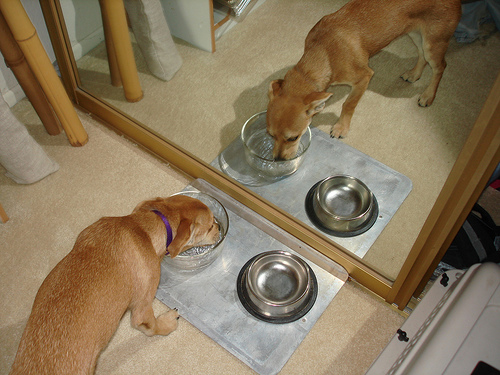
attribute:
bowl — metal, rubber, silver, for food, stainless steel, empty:
[236, 252, 317, 325]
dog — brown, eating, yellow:
[12, 196, 221, 372]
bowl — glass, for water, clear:
[158, 191, 229, 269]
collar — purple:
[149, 205, 176, 258]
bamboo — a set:
[1, 1, 91, 146]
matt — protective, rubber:
[138, 179, 351, 374]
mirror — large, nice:
[41, 1, 499, 309]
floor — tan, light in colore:
[1, 92, 412, 372]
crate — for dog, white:
[364, 261, 500, 374]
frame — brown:
[386, 1, 499, 313]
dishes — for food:
[160, 189, 321, 325]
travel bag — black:
[436, 201, 498, 268]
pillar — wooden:
[103, 2, 145, 101]